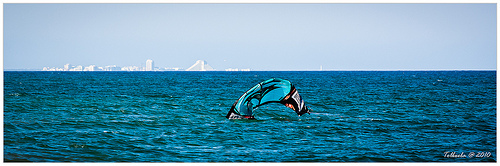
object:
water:
[4, 70, 500, 163]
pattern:
[224, 77, 312, 120]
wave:
[91, 130, 155, 154]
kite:
[226, 77, 312, 119]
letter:
[442, 150, 491, 159]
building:
[183, 59, 216, 72]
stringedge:
[298, 114, 303, 121]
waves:
[337, 82, 476, 140]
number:
[475, 152, 491, 158]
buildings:
[42, 63, 84, 71]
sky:
[1, 0, 495, 71]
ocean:
[2, 71, 494, 164]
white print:
[40, 56, 251, 71]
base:
[226, 77, 313, 121]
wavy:
[149, 94, 207, 122]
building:
[145, 59, 154, 71]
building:
[101, 65, 121, 71]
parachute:
[225, 77, 310, 120]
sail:
[225, 77, 309, 120]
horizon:
[2, 67, 496, 72]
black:
[250, 92, 264, 97]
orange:
[285, 103, 296, 111]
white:
[291, 90, 301, 100]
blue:
[268, 92, 277, 99]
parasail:
[226, 77, 310, 120]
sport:
[224, 77, 313, 120]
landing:
[202, 109, 347, 149]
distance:
[8, 45, 498, 80]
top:
[240, 77, 301, 96]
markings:
[255, 81, 273, 105]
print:
[284, 88, 308, 111]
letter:
[280, 88, 312, 116]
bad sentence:
[352, 116, 373, 125]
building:
[320, 64, 323, 71]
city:
[42, 58, 252, 71]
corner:
[228, 112, 244, 120]